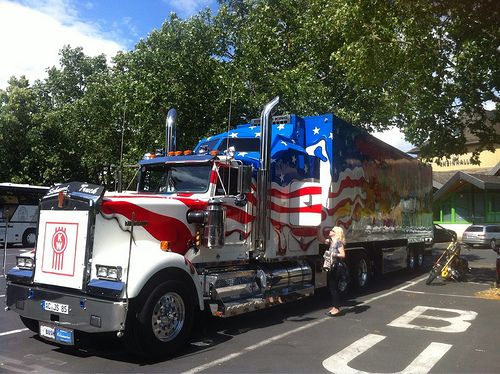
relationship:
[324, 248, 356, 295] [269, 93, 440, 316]
wheel of trailer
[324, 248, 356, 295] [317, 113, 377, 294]
wheel on front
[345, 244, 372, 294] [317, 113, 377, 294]
wheel on front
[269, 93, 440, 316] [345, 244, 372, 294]
trailer front wheel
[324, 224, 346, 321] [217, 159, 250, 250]
woman by door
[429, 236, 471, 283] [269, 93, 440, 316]
motorbike by trailer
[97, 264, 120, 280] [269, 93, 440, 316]
left light on trailer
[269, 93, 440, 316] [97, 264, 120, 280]
trailer has left light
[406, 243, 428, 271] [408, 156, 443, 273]
wheels in back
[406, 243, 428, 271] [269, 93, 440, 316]
wheels of trailer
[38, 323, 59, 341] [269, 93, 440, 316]
plate on trailer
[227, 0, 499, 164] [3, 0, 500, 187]
branches on tree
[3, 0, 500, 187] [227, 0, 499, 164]
tree has branches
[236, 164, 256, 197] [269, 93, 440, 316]
mirror on trailer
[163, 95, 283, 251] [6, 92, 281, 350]
pipes on cab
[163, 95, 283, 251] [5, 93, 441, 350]
pipes on vehicle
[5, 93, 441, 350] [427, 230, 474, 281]
vehicle by motorcycle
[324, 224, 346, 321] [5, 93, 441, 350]
woman by vehicle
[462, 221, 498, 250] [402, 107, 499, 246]
car by building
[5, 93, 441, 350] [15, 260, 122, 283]
vehicle has headlights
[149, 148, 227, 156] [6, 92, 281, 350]
lights on cab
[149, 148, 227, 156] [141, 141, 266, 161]
lights on top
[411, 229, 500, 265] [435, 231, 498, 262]
part of road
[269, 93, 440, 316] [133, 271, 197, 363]
trailer front wheel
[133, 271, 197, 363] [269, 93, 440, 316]
wheel on trailer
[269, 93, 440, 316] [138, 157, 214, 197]
trailer has window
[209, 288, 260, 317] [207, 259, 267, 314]
steps on staircase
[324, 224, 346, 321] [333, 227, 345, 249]
woman has hair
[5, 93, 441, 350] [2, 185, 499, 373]
vehicle in lot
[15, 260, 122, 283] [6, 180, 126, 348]
headlights in front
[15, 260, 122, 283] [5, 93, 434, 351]
headlights on vehicle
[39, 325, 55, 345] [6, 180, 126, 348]
plates on front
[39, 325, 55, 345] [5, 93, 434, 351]
plates on vehicle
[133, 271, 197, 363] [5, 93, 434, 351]
wheel on vehicle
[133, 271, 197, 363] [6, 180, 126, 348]
wheel in front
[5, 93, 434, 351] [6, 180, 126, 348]
vehicle has front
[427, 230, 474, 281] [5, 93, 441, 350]
motorcycle near vehicle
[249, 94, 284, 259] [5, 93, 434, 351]
pipe on vehicle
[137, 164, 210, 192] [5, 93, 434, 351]
windshield on vehicle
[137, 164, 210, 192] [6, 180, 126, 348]
windshield in front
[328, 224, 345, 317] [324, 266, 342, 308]
person wears pants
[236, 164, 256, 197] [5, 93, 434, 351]
mirror on vehicle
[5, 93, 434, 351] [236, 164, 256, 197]
vehicle has mirror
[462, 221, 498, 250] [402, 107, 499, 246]
car near building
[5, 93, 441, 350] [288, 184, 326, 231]
vehicle has compartment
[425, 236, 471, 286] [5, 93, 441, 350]
motorbike near vehicle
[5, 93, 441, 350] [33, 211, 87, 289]
vehicle has cover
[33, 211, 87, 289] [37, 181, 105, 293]
cover on grill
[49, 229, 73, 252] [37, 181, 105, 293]
kw on grill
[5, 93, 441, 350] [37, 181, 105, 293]
vehicle has grill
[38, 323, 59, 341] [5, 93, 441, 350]
plate on vehicle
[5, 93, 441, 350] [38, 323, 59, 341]
vehicle has plate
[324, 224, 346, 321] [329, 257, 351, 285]
woman holds purse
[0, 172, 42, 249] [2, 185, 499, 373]
bus in lot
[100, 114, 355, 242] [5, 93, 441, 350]
flag on vehicle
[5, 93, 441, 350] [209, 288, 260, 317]
vehicle has steps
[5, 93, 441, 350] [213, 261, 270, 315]
vehicle has boards